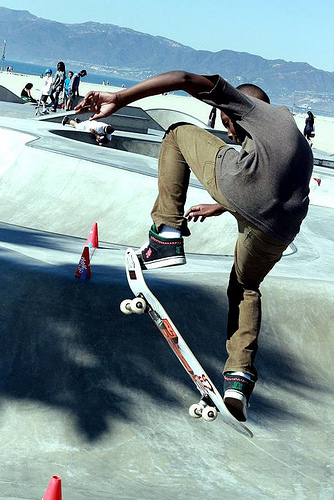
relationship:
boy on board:
[96, 70, 314, 423] [125, 244, 253, 439]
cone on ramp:
[41, 468, 68, 495] [2, 212, 321, 497]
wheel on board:
[202, 406, 217, 422] [125, 244, 253, 439]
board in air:
[125, 244, 253, 439] [103, 228, 263, 378]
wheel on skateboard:
[130, 297, 147, 315] [116, 241, 255, 445]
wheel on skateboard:
[120, 298, 133, 314] [116, 241, 255, 445]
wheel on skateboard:
[203, 405, 217, 423] [116, 241, 255, 445]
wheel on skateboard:
[189, 404, 202, 418] [116, 241, 255, 445]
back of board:
[127, 281, 227, 421] [125, 244, 253, 439]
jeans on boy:
[131, 121, 299, 376] [96, 70, 314, 423]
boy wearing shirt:
[96, 70, 314, 423] [190, 70, 315, 245]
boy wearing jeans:
[96, 71, 321, 441] [131, 121, 299, 376]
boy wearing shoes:
[96, 70, 314, 423] [138, 229, 258, 421]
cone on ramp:
[74, 246, 90, 278] [3, 279, 332, 498]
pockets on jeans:
[245, 227, 281, 279] [131, 121, 297, 351]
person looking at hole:
[60, 115, 112, 144] [49, 127, 162, 157]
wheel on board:
[128, 296, 147, 314] [113, 244, 253, 445]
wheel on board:
[117, 298, 133, 314] [113, 244, 253, 445]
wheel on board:
[202, 406, 217, 422] [113, 244, 253, 445]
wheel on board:
[188, 402, 201, 415] [113, 244, 253, 445]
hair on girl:
[307, 109, 314, 125] [302, 109, 315, 148]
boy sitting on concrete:
[96, 70, 314, 423] [1, 85, 331, 498]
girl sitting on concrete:
[304, 111, 316, 147] [1, 85, 331, 498]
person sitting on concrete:
[20, 78, 40, 102] [1, 85, 331, 498]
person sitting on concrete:
[45, 59, 67, 112] [1, 85, 331, 498]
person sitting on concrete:
[65, 67, 86, 108] [1, 85, 331, 498]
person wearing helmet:
[62, 115, 114, 144] [42, 66, 51, 76]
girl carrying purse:
[304, 111, 316, 147] [309, 125, 317, 138]